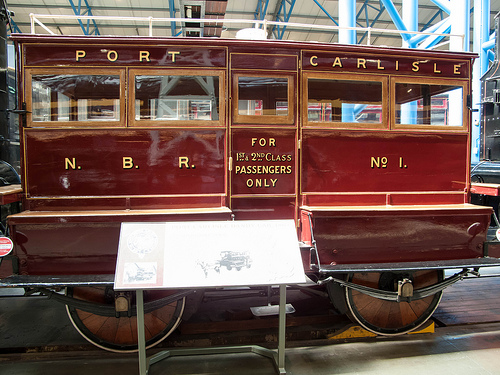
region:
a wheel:
[317, 272, 401, 334]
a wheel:
[352, 269, 392, 342]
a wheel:
[314, 242, 475, 370]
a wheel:
[322, 241, 413, 319]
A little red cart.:
[15, 26, 495, 333]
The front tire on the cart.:
[51, 283, 186, 366]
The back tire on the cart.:
[313, 261, 495, 357]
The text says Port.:
[71, 36, 191, 66]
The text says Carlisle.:
[307, 47, 469, 74]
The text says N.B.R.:
[45, 131, 206, 183]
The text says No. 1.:
[347, 141, 428, 179]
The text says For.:
[236, 128, 281, 148]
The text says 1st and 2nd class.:
[232, 145, 292, 162]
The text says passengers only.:
[231, 162, 291, 189]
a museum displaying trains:
[6, 0, 498, 370]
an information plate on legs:
[113, 219, 307, 289]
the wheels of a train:
[46, 270, 478, 349]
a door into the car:
[226, 49, 302, 284]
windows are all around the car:
[25, 64, 472, 139]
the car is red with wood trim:
[12, 31, 499, 296]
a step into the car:
[249, 290, 299, 327]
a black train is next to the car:
[477, 15, 499, 237]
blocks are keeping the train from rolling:
[321, 320, 443, 346]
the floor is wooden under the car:
[181, 267, 496, 349]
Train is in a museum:
[6, 10, 496, 351]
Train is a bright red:
[6, 20, 496, 280]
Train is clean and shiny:
[5, 40, 493, 286]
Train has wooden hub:
[343, 264, 459, 341]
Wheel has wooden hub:
[64, 277, 194, 354]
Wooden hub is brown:
[343, 264, 460, 341]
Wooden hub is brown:
[62, 277, 194, 353]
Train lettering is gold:
[11, 26, 486, 83]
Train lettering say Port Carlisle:
[53, 44, 473, 82]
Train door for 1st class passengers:
[232, 55, 300, 212]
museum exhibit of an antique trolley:
[17, 18, 488, 351]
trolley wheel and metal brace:
[325, 261, 467, 336]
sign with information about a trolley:
[115, 220, 305, 290]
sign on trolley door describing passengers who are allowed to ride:
[230, 125, 292, 195]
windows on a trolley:
[25, 70, 466, 125]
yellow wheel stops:
[321, 323, 436, 339]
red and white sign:
[0, 234, 12, 254]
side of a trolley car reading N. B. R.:
[20, 128, 226, 198]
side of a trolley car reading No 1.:
[302, 131, 467, 198]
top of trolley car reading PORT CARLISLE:
[22, 48, 466, 78]